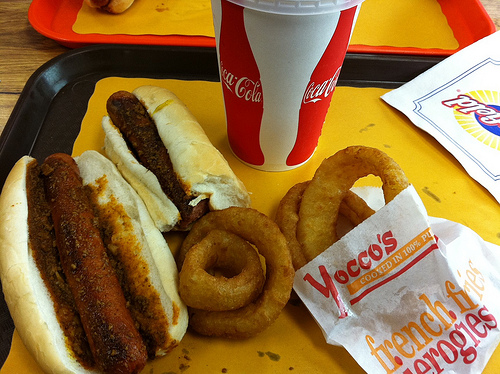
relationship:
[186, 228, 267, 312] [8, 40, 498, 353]
onion ring on tray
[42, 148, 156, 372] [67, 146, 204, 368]
hotdog on bun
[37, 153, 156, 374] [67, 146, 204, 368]
hotdog are in bun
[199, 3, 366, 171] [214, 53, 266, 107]
cup says coca-cola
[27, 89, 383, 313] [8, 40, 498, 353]
food on tray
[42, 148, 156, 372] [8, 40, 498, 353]
hotdog on tray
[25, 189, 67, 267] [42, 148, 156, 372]
chili on hotdog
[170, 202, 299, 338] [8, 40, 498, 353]
onion rings on tray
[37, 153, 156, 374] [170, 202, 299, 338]
hotdog are by onion rings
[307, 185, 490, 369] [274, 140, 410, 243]
bag holds onion rings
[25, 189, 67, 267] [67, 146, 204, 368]
chili on bun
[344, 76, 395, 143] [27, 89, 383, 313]
paper under food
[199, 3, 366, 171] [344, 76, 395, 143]
cup on paper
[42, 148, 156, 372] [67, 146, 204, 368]
hotdog inside bun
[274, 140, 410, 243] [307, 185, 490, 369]
onion rings are in a bag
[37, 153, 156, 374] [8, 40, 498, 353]
hotdog are on tray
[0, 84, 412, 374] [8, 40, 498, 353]
food on tray